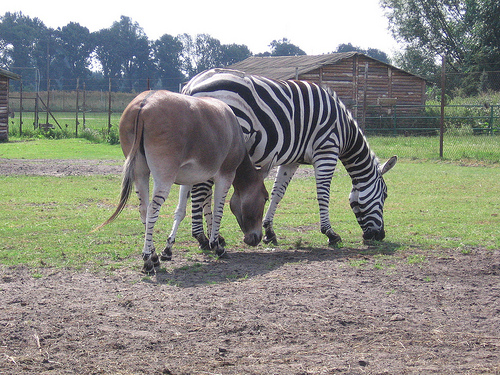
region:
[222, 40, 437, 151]
log cabin behind zebra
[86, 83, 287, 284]
zebroid grazing in field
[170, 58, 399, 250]
zebra grazing in field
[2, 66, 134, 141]
fencing behind two animals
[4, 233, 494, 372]
bare patch of earth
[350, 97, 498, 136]
fencing in front of log building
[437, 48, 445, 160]
tall wood pole in field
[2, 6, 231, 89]
hazy treeline in distance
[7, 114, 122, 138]
flowers growing along fenceline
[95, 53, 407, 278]
two animals grazing in field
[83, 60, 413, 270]
two beautiful zebras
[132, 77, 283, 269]
this one is a baby as he doesnt have his stripes yet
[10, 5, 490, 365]
the zebras are trying to graze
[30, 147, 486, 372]
grazing area appears to be pretty scarce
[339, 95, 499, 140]
the entire area is fenced in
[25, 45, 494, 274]
these zebras are being kept in captivity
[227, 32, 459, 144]
the building in the back seems old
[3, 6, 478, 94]
many trees are in the background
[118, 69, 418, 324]
a mother zebra & her baby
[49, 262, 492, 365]
nothing but brown dirt.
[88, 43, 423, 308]
two zebras grazing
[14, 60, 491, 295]
the one is just a baby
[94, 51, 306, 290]
he hasnt gotten his stripes as yet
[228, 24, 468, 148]
the building in the background appears to be old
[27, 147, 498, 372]
there doesnt appear to be much to graze upon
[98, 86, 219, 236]
the baby has a black stripe down his back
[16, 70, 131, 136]
these animals are fenced in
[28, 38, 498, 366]
this entire scenario is wrong - they shouldnt be fenced in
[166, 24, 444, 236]
the zebras are so beautiful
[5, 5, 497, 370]
the zebras do not look happy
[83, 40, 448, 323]
a brown and a black and white donkey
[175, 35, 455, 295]
zebra with black and white stripes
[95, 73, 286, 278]
brown zebra with striped legs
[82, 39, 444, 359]
animals grazing in the grass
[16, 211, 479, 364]
patch of dirt and dead grass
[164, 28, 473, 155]
small wood building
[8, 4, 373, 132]
line of trees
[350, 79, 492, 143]
fence surrounding a field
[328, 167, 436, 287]
zebra eating grass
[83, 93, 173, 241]
tail with long hair flowing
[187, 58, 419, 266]
zebra with white stripes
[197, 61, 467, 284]
zebra with black stripes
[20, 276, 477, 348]
bare gound no grass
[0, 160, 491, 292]
patch of green grass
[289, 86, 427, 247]
zebra with a ear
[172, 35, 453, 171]
brown wooden barn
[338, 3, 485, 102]
beautiful large green tree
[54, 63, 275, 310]
animal with a long tail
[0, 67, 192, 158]
fence row with wooden posts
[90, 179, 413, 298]
eight animal hoofs